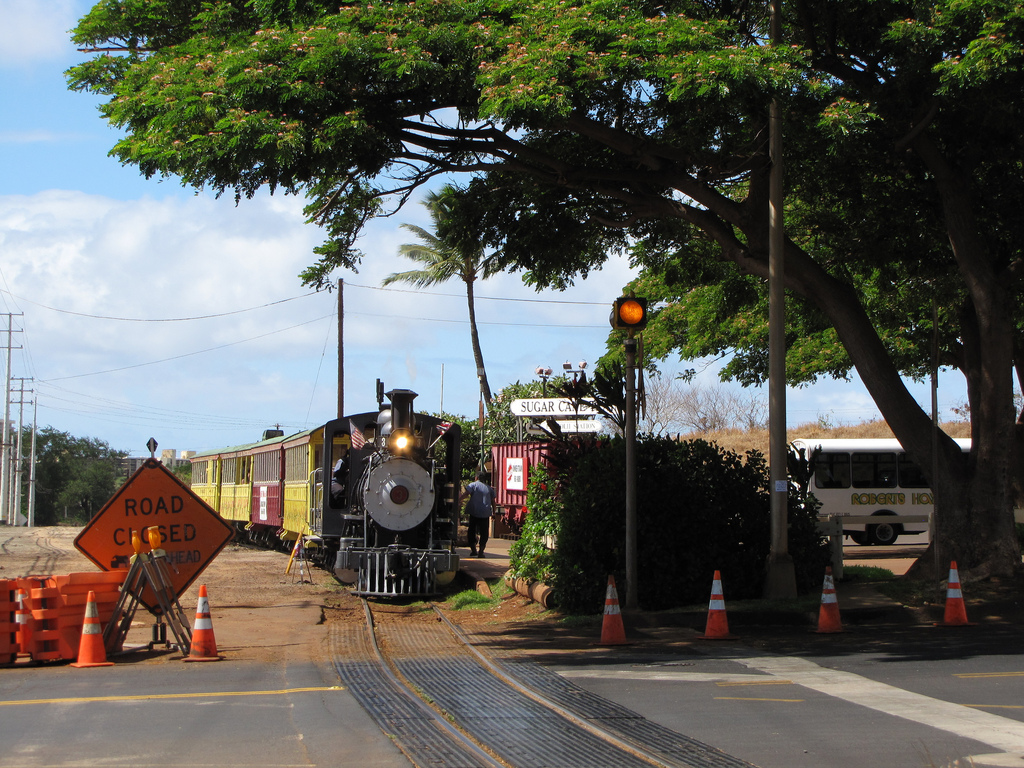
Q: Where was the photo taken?
A: In front of a railway.